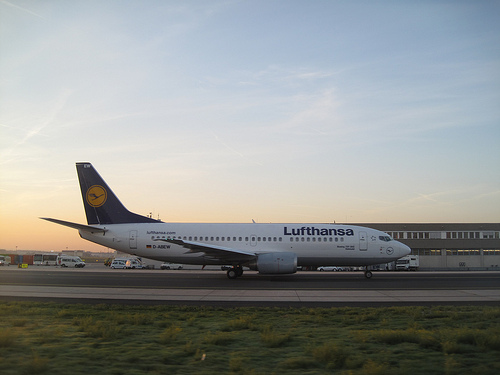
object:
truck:
[396, 255, 420, 272]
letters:
[284, 227, 291, 236]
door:
[359, 231, 368, 251]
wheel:
[233, 266, 243, 277]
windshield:
[379, 236, 393, 241]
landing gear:
[227, 264, 243, 280]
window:
[257, 237, 261, 242]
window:
[245, 237, 249, 242]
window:
[323, 237, 326, 242]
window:
[263, 237, 267, 242]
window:
[233, 237, 237, 242]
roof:
[343, 222, 500, 231]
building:
[1, 249, 34, 264]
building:
[62, 249, 108, 262]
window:
[279, 237, 282, 242]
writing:
[346, 229, 354, 236]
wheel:
[333, 268, 337, 272]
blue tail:
[76, 161, 165, 225]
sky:
[3, 1, 497, 126]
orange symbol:
[86, 185, 108, 208]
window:
[273, 237, 277, 242]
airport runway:
[1, 267, 500, 305]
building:
[318, 222, 500, 271]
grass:
[0, 301, 498, 373]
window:
[379, 235, 394, 241]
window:
[239, 237, 242, 241]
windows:
[295, 237, 299, 242]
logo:
[284, 227, 354, 236]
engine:
[257, 252, 298, 274]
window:
[318, 237, 321, 242]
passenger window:
[340, 237, 344, 242]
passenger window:
[290, 237, 293, 242]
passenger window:
[329, 237, 332, 242]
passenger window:
[307, 237, 310, 242]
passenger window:
[301, 237, 305, 242]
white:
[233, 223, 257, 233]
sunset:
[4, 223, 50, 246]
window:
[252, 237, 256, 242]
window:
[227, 237, 230, 242]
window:
[268, 237, 271, 242]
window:
[335, 237, 338, 242]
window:
[312, 237, 316, 242]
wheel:
[227, 268, 238, 279]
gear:
[365, 271, 373, 279]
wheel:
[338, 268, 342, 272]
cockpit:
[378, 235, 393, 243]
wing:
[152, 238, 257, 262]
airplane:
[40, 162, 411, 279]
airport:
[0, 222, 500, 311]